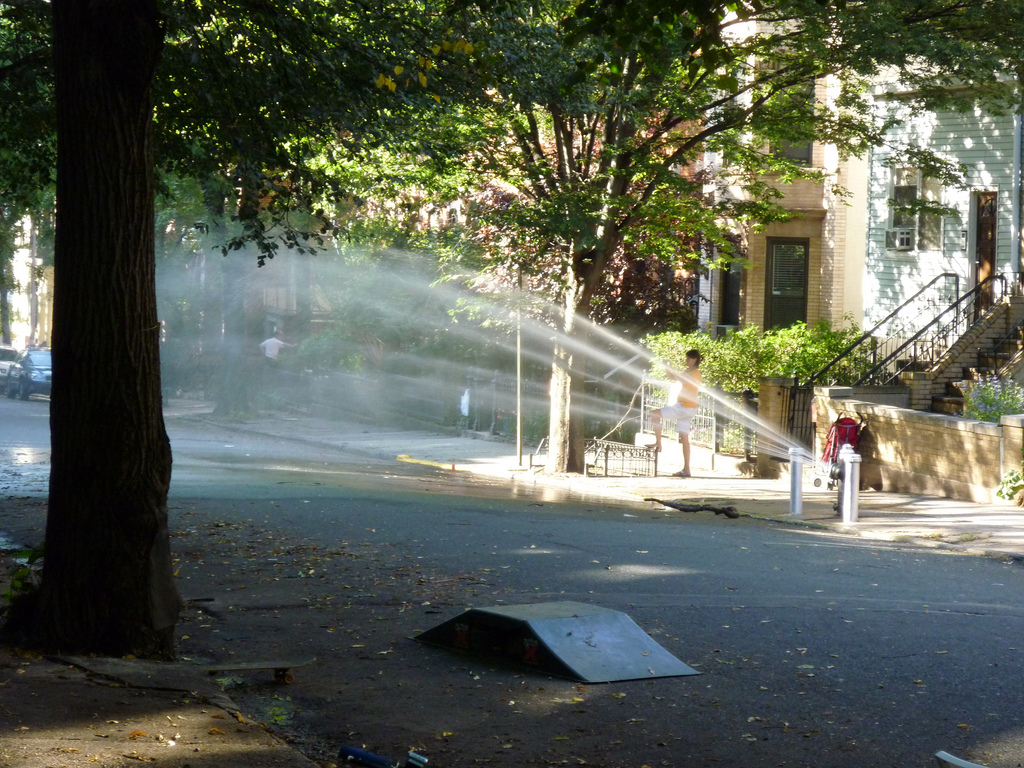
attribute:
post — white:
[840, 453, 866, 527]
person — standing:
[663, 346, 706, 482]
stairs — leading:
[777, 269, 1012, 456]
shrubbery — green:
[629, 316, 871, 394]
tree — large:
[2, 0, 664, 665]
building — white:
[692, 0, 860, 484]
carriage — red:
[808, 406, 869, 499]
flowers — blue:
[945, 367, 1022, 415]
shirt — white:
[249, 311, 316, 383]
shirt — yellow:
[653, 354, 716, 415]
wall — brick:
[814, 407, 992, 505]